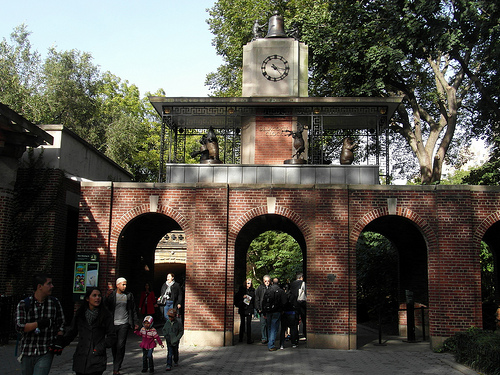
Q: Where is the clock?
A: On the building.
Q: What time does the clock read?
A: 3:25 PM.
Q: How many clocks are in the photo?
A: One.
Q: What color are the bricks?
A: Maroon.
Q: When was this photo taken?
A: Daytime.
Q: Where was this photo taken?
A: Outside in the park.